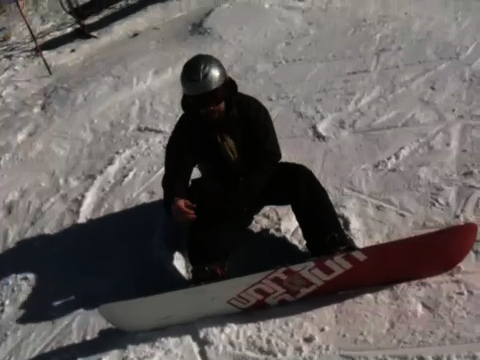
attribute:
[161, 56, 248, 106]
helmet — silver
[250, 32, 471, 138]
snow — White 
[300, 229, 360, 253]
boot — Black 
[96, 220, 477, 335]
snowboard — red and white, white , Red 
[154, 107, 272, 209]
coat — black 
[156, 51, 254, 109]
helmet — silver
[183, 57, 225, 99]
helmet — black , Silver 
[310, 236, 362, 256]
foot — mans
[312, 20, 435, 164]
snow — white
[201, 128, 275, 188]
hand — covered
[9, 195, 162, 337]
shadow — person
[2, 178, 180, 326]
shadow — snowboarder